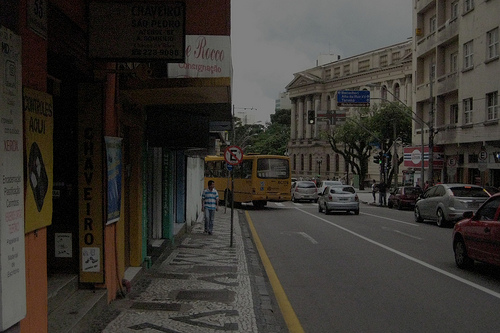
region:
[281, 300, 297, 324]
THE LINE IS YELLOW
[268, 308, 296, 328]
THE LINE IS YELLOW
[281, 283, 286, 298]
THE LINE IS YELLOW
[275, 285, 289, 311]
THE LINE IS YELLOW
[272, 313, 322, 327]
THE LINE IS YELLOW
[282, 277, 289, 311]
THE LINE IS YELLOW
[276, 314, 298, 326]
THE LINE IS YELLOW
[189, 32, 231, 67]
white sign with red writing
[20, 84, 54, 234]
yellow advertisement sign in Spanish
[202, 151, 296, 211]
yellow bus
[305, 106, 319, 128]
traffic light in the distance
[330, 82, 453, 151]
street sign attached to poles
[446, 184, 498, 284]
front end of a red car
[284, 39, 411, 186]
stone building in the distance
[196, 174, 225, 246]
man wearing a blue and white striped shirt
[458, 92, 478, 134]
rectangular window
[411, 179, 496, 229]
silver car seen from behind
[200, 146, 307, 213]
a yellow bus turning a corner.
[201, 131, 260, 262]
A no parking sign.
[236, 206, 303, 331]
a yellow line on a road.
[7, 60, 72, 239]
a sign in front of a building.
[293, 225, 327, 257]
a white line on a road.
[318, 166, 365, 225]
a car driving down a street.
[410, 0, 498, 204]
a tall multi story building.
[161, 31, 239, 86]
a sign on a building.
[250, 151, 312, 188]
a window on a bus.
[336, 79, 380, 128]
a blue sign.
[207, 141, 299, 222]
yellow bus turning corner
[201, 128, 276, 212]
white street sign on a pole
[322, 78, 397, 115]
blue street sign with white lettering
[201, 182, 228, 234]
person in blue and white shirt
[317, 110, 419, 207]
several trees on sidewalk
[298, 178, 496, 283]
several cars driving on street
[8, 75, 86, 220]
yellow sign with black lettering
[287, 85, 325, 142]
traffic light with green light on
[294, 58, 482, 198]
tan buildings in background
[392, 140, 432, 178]
red and white sign on building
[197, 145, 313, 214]
bus turning the corner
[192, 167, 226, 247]
man walking down the sidewalk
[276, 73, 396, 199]
large building on the right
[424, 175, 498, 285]
red car on street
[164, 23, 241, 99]
sign displayed above business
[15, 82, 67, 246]
yellow and black sign on doorway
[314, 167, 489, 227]
two silver cars on street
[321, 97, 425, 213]
two full trees on curb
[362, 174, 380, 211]
person standing on the curb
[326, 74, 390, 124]
blue and white traffic sign